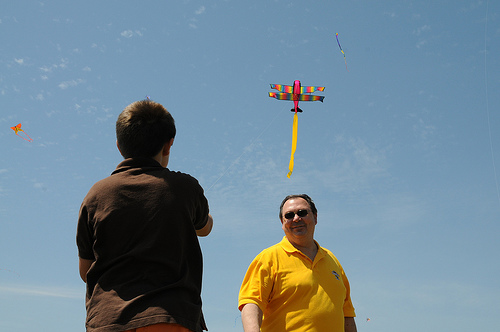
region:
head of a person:
[81, 83, 212, 180]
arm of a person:
[77, 210, 111, 257]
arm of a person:
[168, 182, 228, 245]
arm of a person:
[223, 267, 291, 325]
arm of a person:
[329, 284, 374, 326]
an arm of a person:
[187, 167, 224, 234]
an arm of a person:
[77, 199, 117, 277]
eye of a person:
[282, 208, 318, 218]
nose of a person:
[285, 210, 308, 225]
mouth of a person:
[292, 221, 313, 235]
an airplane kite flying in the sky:
[263, 75, 330, 116]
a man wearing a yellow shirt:
[231, 186, 361, 326]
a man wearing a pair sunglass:
[245, 191, 355, 281]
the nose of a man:
[290, 206, 302, 222]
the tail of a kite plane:
[281, 106, 301, 181]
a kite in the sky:
[8, 119, 25, 139]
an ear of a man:
[161, 129, 178, 156]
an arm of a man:
[238, 248, 275, 330]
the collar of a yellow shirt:
[279, 234, 301, 259]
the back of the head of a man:
[105, 94, 189, 170]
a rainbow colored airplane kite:
[268, 78, 325, 114]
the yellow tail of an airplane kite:
[286, 113, 299, 176]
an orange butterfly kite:
[9, 123, 25, 134]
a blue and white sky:
[0, 1, 498, 330]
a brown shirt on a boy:
[76, 157, 211, 330]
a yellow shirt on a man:
[238, 234, 357, 330]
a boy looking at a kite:
[73, 97, 213, 328]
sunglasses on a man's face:
[280, 205, 310, 215]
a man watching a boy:
[236, 192, 357, 328]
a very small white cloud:
[122, 29, 132, 38]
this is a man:
[229, 179, 369, 330]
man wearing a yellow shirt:
[230, 239, 365, 330]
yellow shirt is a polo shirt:
[228, 211, 373, 330]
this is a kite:
[250, 67, 361, 209]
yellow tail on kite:
[272, 97, 334, 192]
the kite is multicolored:
[254, 59, 337, 118]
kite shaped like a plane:
[251, 62, 340, 121]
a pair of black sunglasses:
[278, 201, 312, 225]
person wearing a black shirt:
[62, 130, 224, 316]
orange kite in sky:
[2, 107, 44, 158]